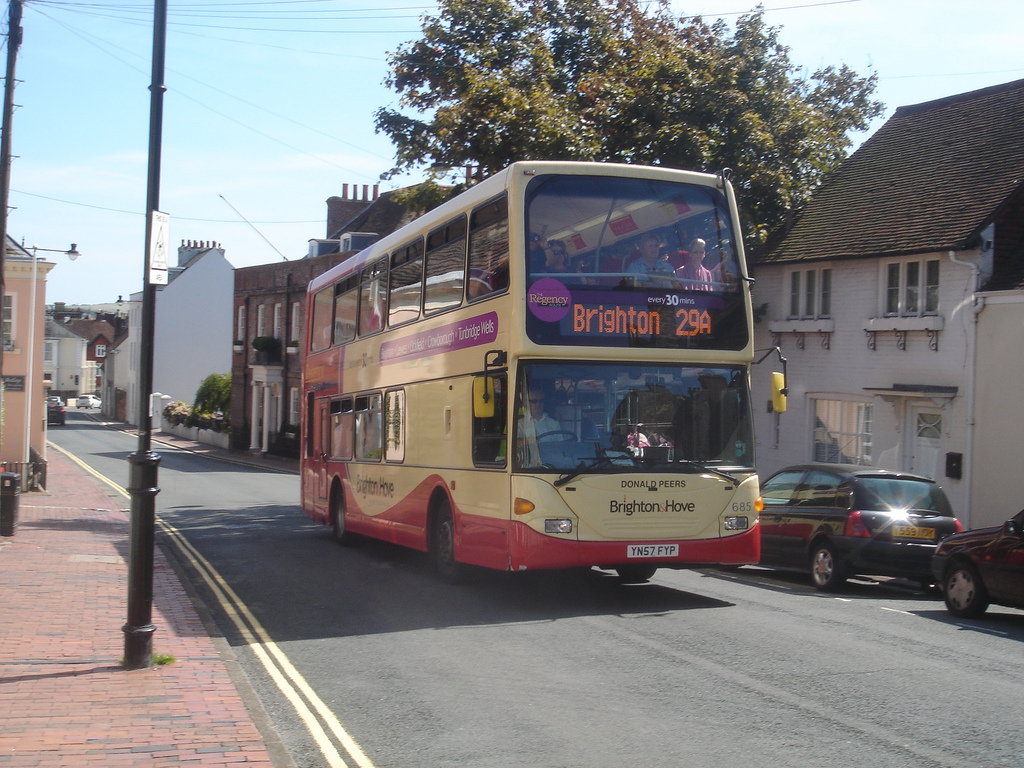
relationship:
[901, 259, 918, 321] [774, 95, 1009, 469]
window on a building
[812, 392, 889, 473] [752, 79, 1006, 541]
window on a building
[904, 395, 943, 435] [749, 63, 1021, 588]
window on a building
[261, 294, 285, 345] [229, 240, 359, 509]
window on a building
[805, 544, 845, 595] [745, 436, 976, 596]
wheel belongs to car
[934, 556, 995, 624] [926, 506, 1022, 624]
wheel belongs to car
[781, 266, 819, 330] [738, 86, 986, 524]
window on side of building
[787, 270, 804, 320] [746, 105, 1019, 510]
window on side of building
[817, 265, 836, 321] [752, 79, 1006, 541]
window on side of building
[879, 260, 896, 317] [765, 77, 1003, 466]
window on side of building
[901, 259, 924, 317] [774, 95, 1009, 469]
window on side of building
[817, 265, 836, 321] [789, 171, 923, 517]
window on building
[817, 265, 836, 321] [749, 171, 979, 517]
window on building